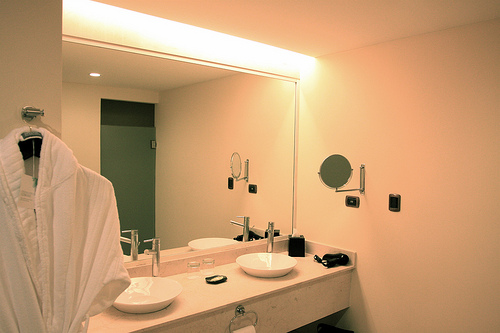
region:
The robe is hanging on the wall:
[1, 107, 131, 332]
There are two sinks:
[110, 216, 297, 318]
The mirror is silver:
[314, 153, 368, 195]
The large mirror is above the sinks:
[56, 32, 309, 315]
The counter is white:
[99, 239, 361, 329]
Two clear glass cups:
[183, 254, 220, 280]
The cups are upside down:
[183, 256, 215, 281]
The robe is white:
[1, 112, 128, 331]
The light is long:
[64, 2, 318, 79]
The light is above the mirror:
[62, 1, 313, 266]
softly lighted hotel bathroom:
[0, 0, 498, 332]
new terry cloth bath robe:
[0, 126, 132, 331]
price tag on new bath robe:
[18, 170, 38, 210]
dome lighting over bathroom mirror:
[46, 0, 322, 81]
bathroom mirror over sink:
[62, 38, 301, 270]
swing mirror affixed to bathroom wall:
[315, 150, 369, 195]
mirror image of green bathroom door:
[95, 93, 165, 254]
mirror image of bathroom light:
[86, 68, 104, 80]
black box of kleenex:
[287, 226, 307, 258]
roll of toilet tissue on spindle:
[226, 304, 261, 331]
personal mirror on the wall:
[316, 154, 365, 197]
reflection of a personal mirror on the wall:
[229, 151, 250, 182]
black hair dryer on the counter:
[315, 248, 352, 269]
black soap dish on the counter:
[204, 273, 227, 285]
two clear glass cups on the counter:
[185, 255, 219, 278]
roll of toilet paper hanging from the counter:
[228, 303, 260, 331]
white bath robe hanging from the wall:
[0, 125, 130, 332]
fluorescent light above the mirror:
[59, 0, 319, 83]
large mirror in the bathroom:
[60, 36, 294, 263]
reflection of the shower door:
[98, 98, 161, 253]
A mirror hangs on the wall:
[310, 139, 368, 198]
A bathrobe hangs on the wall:
[10, 81, 134, 329]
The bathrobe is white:
[4, 86, 146, 321]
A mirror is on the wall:
[52, 46, 345, 244]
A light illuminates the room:
[61, 0, 334, 117]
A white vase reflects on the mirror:
[170, 225, 252, 269]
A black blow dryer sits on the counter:
[312, 244, 363, 283]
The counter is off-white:
[93, 213, 357, 323]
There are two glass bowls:
[110, 241, 307, 316]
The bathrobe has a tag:
[10, 123, 46, 220]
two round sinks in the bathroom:
[110, 251, 297, 312]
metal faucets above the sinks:
[142, 220, 276, 277]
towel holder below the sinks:
[226, 304, 258, 331]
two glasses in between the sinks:
[187, 255, 215, 277]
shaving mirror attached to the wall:
[315, 151, 365, 194]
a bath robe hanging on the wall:
[0, 123, 130, 331]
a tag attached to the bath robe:
[17, 174, 38, 207]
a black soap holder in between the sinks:
[204, 273, 226, 283]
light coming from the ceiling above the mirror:
[62, 0, 317, 75]